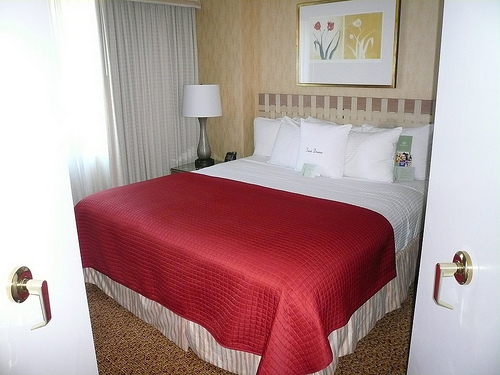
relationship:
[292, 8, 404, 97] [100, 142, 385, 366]
picture hanging over a bed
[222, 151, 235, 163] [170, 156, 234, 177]
clock on a bed side table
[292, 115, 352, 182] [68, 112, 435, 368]
pillow on bed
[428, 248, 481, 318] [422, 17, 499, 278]
gold handle on door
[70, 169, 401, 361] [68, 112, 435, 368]
bedspread on bed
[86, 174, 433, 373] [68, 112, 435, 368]
quilt on bed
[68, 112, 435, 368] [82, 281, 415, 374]
bed on carpet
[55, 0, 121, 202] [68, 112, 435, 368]
window beside bed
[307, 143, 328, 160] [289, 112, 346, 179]
words on pillow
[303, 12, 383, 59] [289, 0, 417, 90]
flowers on picture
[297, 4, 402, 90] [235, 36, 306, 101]
picture on wall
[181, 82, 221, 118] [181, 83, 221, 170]
shade on lamp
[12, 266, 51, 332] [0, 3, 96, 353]
handle on door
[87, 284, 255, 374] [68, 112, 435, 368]
bedskirt around bed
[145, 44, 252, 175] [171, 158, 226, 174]
lamp on table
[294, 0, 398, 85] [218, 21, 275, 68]
picture on wall.